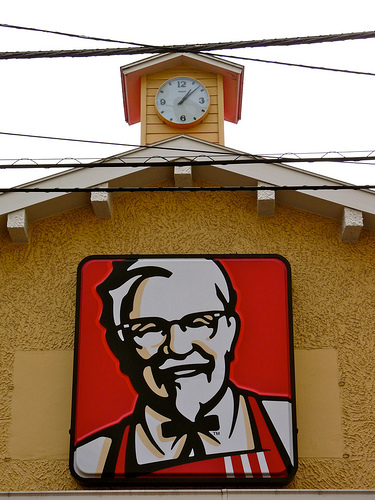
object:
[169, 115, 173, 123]
7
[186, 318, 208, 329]
eye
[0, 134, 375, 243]
roof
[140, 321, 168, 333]
eye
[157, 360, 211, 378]
mouth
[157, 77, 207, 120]
face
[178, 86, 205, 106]
hands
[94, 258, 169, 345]
hair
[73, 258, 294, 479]
comic person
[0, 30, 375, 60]
rope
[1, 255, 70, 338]
wall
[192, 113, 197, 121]
5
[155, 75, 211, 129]
clock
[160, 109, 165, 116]
number 8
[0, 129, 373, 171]
wires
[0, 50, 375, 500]
building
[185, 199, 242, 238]
wall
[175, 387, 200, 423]
beard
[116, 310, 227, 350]
glasses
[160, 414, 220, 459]
bowtie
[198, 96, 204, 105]
3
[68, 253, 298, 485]
frame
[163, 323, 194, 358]
nose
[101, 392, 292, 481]
apron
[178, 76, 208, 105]
1:08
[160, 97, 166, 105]
number